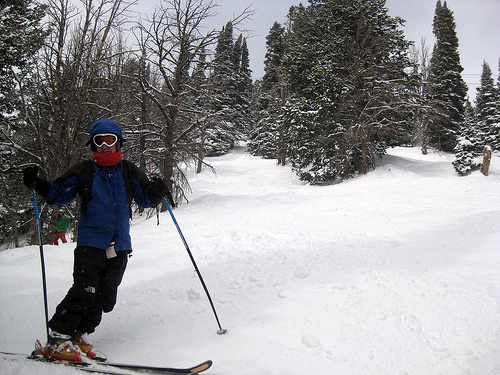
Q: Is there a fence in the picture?
A: No, there are no fences.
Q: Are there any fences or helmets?
A: No, there are no fences or helmets.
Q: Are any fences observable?
A: No, there are no fences.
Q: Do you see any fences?
A: No, there are no fences.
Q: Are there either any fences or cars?
A: No, there are no fences or cars.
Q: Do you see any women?
A: Yes, there is a woman.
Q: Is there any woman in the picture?
A: Yes, there is a woman.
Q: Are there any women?
A: Yes, there is a woman.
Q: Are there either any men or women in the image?
A: Yes, there is a woman.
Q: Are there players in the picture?
A: No, there are no players.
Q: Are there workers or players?
A: No, there are no players or workers.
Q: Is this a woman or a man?
A: This is a woman.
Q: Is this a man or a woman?
A: This is a woman.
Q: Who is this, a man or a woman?
A: This is a woman.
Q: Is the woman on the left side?
A: Yes, the woman is on the left of the image.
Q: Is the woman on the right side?
A: No, the woman is on the left of the image.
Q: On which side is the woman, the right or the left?
A: The woman is on the left of the image.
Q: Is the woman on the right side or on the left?
A: The woman is on the left of the image.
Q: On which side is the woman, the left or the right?
A: The woman is on the left of the image.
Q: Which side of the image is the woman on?
A: The woman is on the left of the image.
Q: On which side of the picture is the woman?
A: The woman is on the left of the image.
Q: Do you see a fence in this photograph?
A: No, there are no fences.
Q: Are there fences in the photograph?
A: No, there are no fences.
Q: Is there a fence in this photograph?
A: No, there are no fences.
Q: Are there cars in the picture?
A: No, there are no cars.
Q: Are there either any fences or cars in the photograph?
A: No, there are no cars or fences.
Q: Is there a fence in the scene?
A: No, there are no fences.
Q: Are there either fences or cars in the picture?
A: No, there are no fences or cars.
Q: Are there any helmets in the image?
A: No, there are no helmets.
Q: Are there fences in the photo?
A: No, there are no fences.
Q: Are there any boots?
A: Yes, there are boots.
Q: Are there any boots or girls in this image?
A: Yes, there are boots.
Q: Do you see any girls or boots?
A: Yes, there are boots.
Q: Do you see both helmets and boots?
A: No, there are boots but no helmets.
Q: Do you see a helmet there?
A: No, there are no helmets.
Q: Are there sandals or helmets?
A: No, there are no helmets or sandals.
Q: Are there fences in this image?
A: No, there are no fences.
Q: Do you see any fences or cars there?
A: No, there are no fences or cars.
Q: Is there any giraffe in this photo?
A: No, there are no giraffes.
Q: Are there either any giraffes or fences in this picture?
A: No, there are no giraffes or fences.